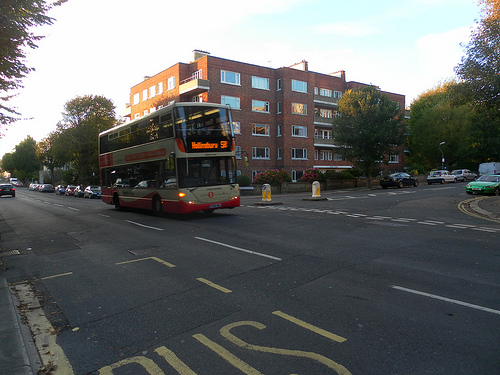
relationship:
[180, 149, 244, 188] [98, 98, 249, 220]
windshield of bus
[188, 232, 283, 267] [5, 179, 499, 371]
line painted on street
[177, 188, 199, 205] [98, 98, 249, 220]
headlights on bus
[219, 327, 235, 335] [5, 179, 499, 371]
paint on street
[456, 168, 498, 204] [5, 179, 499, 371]
car parked on street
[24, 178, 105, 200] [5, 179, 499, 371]
cars parked on street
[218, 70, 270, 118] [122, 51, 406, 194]
windows on building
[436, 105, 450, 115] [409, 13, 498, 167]
leaves in trees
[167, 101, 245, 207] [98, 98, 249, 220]
front of bus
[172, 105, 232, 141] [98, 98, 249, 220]
window of bus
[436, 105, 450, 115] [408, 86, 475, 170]
leaves on tree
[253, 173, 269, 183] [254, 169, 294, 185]
flowers in bush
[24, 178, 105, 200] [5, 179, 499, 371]
cars parked on road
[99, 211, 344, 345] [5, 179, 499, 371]
lines in road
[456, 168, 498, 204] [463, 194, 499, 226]
car by corner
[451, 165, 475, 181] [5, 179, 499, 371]
sedan parked on street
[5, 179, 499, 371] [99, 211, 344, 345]
asphalt with marking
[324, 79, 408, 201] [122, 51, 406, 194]
tree in front of building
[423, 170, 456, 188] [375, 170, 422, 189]
car behind car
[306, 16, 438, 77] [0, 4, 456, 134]
clouds in sky